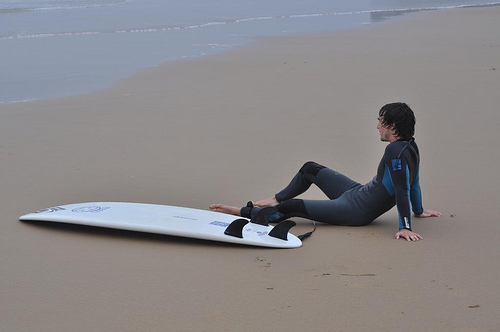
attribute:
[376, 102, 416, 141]
head — black, wet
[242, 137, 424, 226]
wet suit — blue, black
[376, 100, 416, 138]
hair — black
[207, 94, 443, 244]
man — black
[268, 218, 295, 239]
fins — black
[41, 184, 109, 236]
logo — circle, black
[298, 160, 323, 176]
patch — black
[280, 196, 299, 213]
patch — black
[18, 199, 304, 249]
board — white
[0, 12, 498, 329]
sand — beach, tan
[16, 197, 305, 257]
surfboard — white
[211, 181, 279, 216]
feet — bare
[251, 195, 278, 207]
foot — bare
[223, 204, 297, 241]
skegs — black, three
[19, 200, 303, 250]
surfboard — white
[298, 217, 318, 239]
cord — tether, black